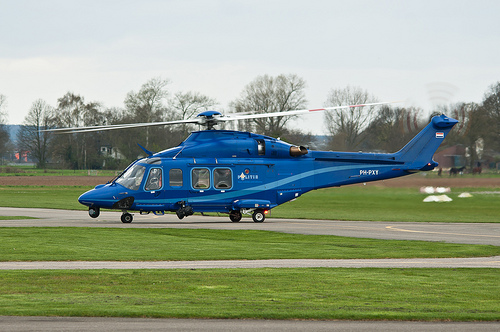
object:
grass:
[0, 263, 499, 319]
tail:
[394, 108, 463, 162]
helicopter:
[71, 110, 460, 225]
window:
[142, 166, 164, 193]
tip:
[73, 179, 120, 211]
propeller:
[28, 99, 411, 135]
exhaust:
[289, 144, 309, 157]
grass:
[2, 223, 498, 263]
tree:
[321, 82, 384, 153]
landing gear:
[120, 210, 134, 223]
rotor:
[23, 115, 204, 138]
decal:
[237, 167, 261, 183]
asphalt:
[3, 206, 498, 246]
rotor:
[401, 81, 477, 149]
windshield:
[111, 162, 151, 191]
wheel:
[251, 209, 268, 223]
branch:
[358, 106, 374, 128]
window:
[167, 167, 186, 189]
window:
[188, 166, 212, 192]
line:
[386, 225, 499, 239]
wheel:
[228, 208, 244, 224]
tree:
[233, 68, 308, 139]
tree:
[15, 96, 64, 172]